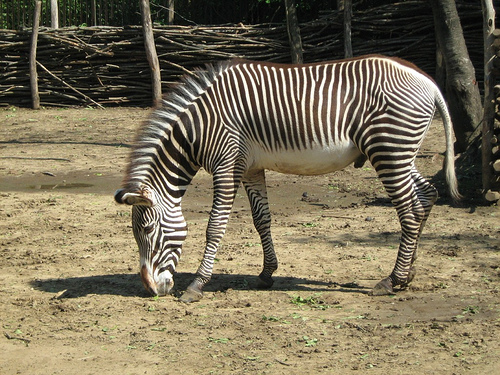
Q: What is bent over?
A: A zebra.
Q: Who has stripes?
A: The zebra.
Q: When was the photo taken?
A: Daytime.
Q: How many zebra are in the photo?
A: One.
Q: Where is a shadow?
A: On the ground.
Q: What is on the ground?
A: Dirt.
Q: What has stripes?
A: Zebra.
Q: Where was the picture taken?
A: In a zoo.